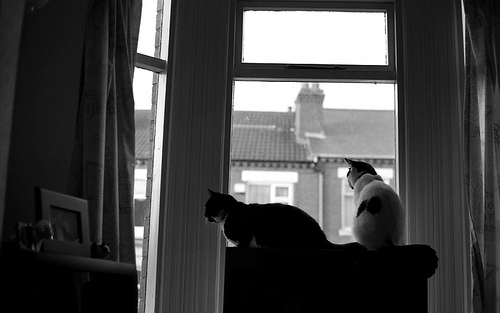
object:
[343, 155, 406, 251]
cat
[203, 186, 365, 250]
cat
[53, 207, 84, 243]
picture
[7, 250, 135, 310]
shelf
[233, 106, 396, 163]
roof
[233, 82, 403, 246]
house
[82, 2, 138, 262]
curtain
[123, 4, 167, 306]
window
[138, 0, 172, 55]
top section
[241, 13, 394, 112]
sky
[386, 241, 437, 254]
tail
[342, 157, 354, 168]
ear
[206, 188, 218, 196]
ear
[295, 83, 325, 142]
chimney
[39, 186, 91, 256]
frame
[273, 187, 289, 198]
window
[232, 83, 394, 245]
building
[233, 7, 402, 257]
window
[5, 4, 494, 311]
photo